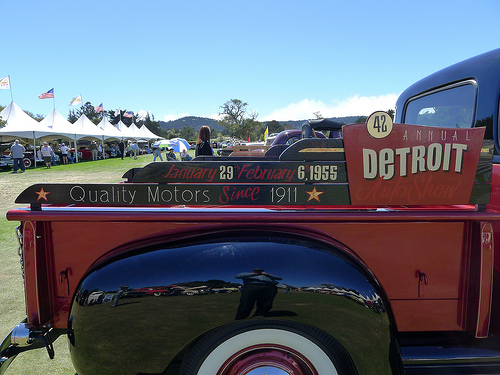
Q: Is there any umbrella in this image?
A: Yes, there is an umbrella.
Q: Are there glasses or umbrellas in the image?
A: Yes, there is an umbrella.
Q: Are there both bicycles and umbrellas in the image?
A: No, there is an umbrella but no bicycles.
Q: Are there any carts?
A: No, there are no carts.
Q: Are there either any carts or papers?
A: No, there are no carts or papers.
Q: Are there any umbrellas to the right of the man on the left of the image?
A: Yes, there is an umbrella to the right of the man.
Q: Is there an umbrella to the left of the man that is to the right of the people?
A: No, the umbrella is to the right of the man.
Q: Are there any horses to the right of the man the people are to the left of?
A: No, there is an umbrella to the right of the man.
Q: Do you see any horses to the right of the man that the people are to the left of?
A: No, there is an umbrella to the right of the man.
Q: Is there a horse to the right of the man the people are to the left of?
A: No, there is an umbrella to the right of the man.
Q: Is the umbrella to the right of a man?
A: Yes, the umbrella is to the right of a man.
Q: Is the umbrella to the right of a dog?
A: No, the umbrella is to the right of a man.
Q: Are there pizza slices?
A: No, there are no pizza slices.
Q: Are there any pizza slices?
A: No, there are no pizza slices.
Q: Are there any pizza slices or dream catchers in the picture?
A: No, there are no pizza slices or dream catchers.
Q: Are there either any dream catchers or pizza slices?
A: No, there are no pizza slices or dream catchers.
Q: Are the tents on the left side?
A: Yes, the tents are on the left of the image.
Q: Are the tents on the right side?
A: No, the tents are on the left of the image.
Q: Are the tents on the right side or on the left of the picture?
A: The tents are on the left of the image.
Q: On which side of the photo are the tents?
A: The tents are on the left of the image.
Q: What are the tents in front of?
A: The tents are in front of the sky.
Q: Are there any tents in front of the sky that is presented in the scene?
A: Yes, there are tents in front of the sky.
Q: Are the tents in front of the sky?
A: Yes, the tents are in front of the sky.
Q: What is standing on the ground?
A: The tents are standing on the ground.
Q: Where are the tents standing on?
A: The tents are standing on the ground.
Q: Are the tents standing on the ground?
A: Yes, the tents are standing on the ground.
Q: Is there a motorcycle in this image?
A: No, there are no motorcycles.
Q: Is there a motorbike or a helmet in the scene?
A: No, there are no motorcycles or helmets.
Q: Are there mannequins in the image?
A: No, there are no mannequins.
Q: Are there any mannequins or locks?
A: No, there are no mannequins or locks.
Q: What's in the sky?
A: The clouds are in the sky.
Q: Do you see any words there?
A: Yes, there are words.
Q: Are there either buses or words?
A: Yes, there are words.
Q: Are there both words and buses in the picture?
A: No, there are words but no buses.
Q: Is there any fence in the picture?
A: No, there are no fences.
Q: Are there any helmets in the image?
A: No, there are no helmets.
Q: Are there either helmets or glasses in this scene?
A: No, there are no helmets or glasses.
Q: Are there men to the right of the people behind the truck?
A: Yes, there is a man to the right of the people.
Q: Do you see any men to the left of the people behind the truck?
A: No, the man is to the right of the people.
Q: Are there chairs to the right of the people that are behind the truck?
A: No, there is a man to the right of the people.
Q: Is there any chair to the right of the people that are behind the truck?
A: No, there is a man to the right of the people.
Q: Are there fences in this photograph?
A: No, there are no fences.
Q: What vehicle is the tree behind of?
A: The tree is behind the truck.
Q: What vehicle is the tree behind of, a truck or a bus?
A: The tree is behind a truck.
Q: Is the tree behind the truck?
A: Yes, the tree is behind the truck.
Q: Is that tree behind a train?
A: No, the tree is behind the truck.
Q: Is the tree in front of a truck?
A: No, the tree is behind a truck.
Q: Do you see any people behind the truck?
A: Yes, there are people behind the truck.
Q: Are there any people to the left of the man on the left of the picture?
A: Yes, there are people to the left of the man.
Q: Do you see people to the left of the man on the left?
A: Yes, there are people to the left of the man.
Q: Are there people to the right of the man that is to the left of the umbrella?
A: No, the people are to the left of the man.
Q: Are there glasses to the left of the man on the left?
A: No, there are people to the left of the man.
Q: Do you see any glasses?
A: No, there are no glasses.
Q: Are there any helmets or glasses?
A: No, there are no glasses or helmets.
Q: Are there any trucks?
A: Yes, there is a truck.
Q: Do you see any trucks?
A: Yes, there is a truck.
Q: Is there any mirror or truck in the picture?
A: Yes, there is a truck.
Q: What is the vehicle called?
A: The vehicle is a truck.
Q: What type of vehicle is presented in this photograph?
A: The vehicle is a truck.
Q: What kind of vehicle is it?
A: The vehicle is a truck.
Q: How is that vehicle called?
A: This is a truck.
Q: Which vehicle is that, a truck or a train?
A: This is a truck.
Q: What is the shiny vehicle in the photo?
A: The vehicle is a truck.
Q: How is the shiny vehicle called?
A: The vehicle is a truck.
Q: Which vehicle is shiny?
A: The vehicle is a truck.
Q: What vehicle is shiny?
A: The vehicle is a truck.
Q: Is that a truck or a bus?
A: That is a truck.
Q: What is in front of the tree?
A: The truck is in front of the tree.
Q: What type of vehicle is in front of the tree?
A: The vehicle is a truck.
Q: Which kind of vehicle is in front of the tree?
A: The vehicle is a truck.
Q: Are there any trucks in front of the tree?
A: Yes, there is a truck in front of the tree.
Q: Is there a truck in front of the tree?
A: Yes, there is a truck in front of the tree.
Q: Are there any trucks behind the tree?
A: No, the truck is in front of the tree.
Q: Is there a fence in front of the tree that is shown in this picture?
A: No, there is a truck in front of the tree.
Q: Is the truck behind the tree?
A: No, the truck is in front of the tree.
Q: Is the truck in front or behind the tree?
A: The truck is in front of the tree.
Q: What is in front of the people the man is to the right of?
A: The truck is in front of the people.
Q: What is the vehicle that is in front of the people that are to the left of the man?
A: The vehicle is a truck.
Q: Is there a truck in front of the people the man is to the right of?
A: Yes, there is a truck in front of the people.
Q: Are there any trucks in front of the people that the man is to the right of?
A: Yes, there is a truck in front of the people.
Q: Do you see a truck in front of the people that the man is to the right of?
A: Yes, there is a truck in front of the people.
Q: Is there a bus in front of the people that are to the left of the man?
A: No, there is a truck in front of the people.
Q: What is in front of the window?
A: The truck is in front of the window.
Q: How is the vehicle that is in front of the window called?
A: The vehicle is a truck.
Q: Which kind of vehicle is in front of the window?
A: The vehicle is a truck.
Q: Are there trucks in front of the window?
A: Yes, there is a truck in front of the window.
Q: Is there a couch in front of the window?
A: No, there is a truck in front of the window.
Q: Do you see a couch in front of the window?
A: No, there is a truck in front of the window.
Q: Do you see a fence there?
A: No, there are no fences.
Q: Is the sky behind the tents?
A: Yes, the sky is behind the tents.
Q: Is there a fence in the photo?
A: No, there are no fences.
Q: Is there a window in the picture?
A: Yes, there is a window.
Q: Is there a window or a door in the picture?
A: Yes, there is a window.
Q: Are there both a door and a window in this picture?
A: No, there is a window but no doors.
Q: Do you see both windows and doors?
A: No, there is a window but no doors.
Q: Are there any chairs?
A: No, there are no chairs.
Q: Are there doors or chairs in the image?
A: No, there are no chairs or doors.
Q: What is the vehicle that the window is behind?
A: The vehicle is a truck.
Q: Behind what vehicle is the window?
A: The window is behind the truck.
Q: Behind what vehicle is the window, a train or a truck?
A: The window is behind a truck.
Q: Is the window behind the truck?
A: Yes, the window is behind the truck.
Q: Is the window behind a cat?
A: No, the window is behind the truck.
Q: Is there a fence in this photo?
A: No, there are no fences.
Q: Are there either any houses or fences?
A: No, there are no fences or houses.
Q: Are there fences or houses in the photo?
A: No, there are no fences or houses.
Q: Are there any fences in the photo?
A: No, there are no fences.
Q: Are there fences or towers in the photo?
A: No, there are no fences or towers.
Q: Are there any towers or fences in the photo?
A: No, there are no fences or towers.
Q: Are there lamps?
A: No, there are no lamps.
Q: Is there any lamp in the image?
A: No, there are no lamps.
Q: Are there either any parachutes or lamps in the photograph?
A: No, there are no lamps or parachutes.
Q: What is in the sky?
A: The clouds are in the sky.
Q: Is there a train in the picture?
A: No, there are no trains.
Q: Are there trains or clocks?
A: No, there are no trains or clocks.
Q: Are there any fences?
A: No, there are no fences.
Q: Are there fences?
A: No, there are no fences.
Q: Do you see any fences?
A: No, there are no fences.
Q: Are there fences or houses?
A: No, there are no fences or houses.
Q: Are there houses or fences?
A: No, there are no fences or houses.